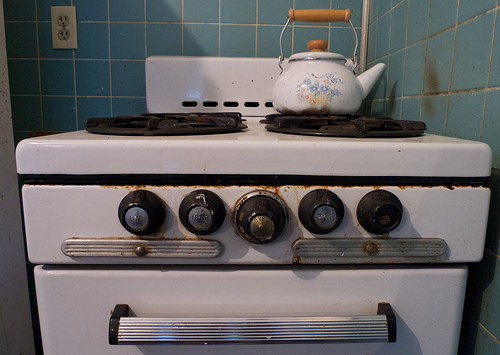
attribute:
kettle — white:
[268, 3, 386, 120]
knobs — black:
[108, 195, 399, 237]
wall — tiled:
[96, 9, 253, 90]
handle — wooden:
[284, 4, 361, 25]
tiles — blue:
[369, 6, 498, 118]